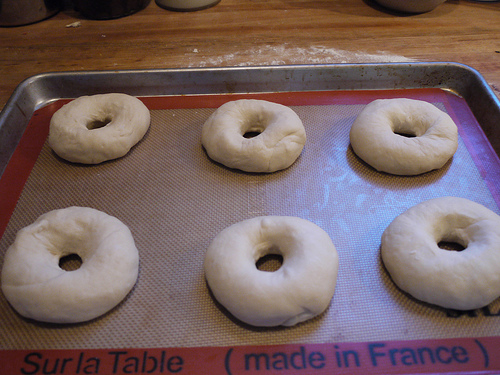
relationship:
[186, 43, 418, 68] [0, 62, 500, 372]
flour above cookie sheet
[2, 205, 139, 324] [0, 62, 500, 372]
dough on cookie sheet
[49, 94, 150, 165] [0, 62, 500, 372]
dough on cookie sheet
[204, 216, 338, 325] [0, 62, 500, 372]
dough on cookie sheet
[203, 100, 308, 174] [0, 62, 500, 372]
dough on cookie sheet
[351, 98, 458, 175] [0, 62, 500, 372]
dough on cookie sheet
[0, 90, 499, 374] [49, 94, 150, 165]
mat under dough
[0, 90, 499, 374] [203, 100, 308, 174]
mat under dough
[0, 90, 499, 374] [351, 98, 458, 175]
mat under dough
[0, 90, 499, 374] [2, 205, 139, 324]
mat under dough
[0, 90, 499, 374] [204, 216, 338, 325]
mat under dough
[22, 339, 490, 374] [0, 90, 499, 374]
writing on top of mat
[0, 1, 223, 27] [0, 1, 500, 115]
cannister on top of table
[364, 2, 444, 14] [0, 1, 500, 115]
cannister on top of table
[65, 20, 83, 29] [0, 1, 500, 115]
crumb on top of table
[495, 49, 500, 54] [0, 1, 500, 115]
marks on top of table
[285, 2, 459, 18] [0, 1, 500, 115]
shadow on table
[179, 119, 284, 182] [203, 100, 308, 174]
shadow next to dough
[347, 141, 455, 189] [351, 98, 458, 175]
shadow next to dough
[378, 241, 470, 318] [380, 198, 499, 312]
shadow next to dough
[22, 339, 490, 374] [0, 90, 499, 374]
writing on mat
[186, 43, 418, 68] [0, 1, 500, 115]
flour on table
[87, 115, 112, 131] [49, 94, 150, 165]
hole in middle of dough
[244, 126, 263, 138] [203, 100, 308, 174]
hole in middle of dough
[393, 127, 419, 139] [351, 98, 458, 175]
hole in middle of dough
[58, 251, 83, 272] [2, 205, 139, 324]
hole in middle of dough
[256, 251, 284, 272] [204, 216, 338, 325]
hole in middle of dough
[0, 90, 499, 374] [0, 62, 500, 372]
food on cookie sheet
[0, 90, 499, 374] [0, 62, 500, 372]
mat on a cookie sheet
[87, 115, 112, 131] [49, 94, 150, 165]
hole in dough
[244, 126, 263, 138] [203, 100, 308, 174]
hole in dough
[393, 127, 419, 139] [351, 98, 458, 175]
hole in dough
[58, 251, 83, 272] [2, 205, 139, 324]
hole in dough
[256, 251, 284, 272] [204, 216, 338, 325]
hole in dough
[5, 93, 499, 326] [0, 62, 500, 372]
food on a cookie sheet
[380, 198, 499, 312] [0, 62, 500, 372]
dough sitting on right cookie sheet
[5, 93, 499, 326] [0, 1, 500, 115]
dough sitting on a table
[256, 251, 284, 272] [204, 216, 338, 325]
hole in middle dough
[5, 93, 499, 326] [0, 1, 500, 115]
food on table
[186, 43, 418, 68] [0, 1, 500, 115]
flour sitting table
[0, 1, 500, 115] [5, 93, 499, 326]
table underneath food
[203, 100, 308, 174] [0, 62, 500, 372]
dough on top cookie sheet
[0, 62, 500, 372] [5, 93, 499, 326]
cookie sheet with food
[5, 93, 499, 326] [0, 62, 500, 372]
food on cookie sheet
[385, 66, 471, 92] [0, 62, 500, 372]
brown spots on cookie sheet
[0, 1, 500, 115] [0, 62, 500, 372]
table underrneath cookie sheet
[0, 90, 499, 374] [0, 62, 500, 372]
mat over cookie sheet